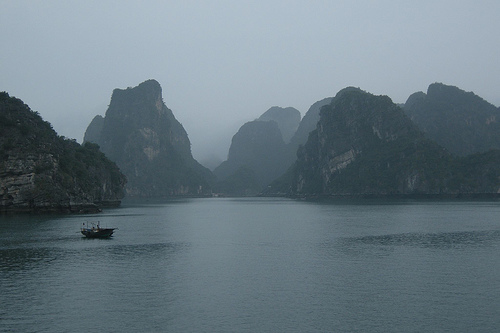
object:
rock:
[265, 77, 485, 229]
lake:
[145, 210, 500, 310]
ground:
[431, 144, 465, 181]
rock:
[59, 62, 427, 208]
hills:
[211, 120, 283, 174]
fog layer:
[82, 78, 297, 158]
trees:
[36, 162, 54, 174]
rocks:
[325, 149, 357, 181]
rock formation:
[100, 79, 213, 198]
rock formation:
[401, 82, 500, 156]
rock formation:
[256, 86, 472, 198]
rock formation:
[0, 91, 129, 214]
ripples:
[29, 253, 171, 313]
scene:
[0, 36, 499, 333]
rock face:
[0, 148, 36, 208]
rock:
[212, 118, 290, 197]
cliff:
[0, 94, 60, 212]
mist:
[182, 117, 234, 167]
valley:
[192, 143, 224, 171]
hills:
[83, 115, 104, 146]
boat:
[81, 220, 115, 238]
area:
[2, 63, 493, 331]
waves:
[0, 195, 499, 332]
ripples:
[331, 215, 496, 299]